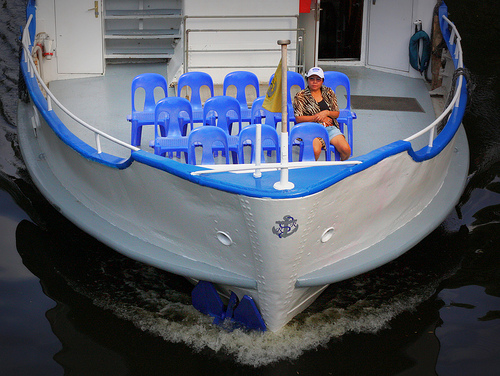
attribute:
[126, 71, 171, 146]
chair — blue, plastic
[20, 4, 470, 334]
boat — blue, white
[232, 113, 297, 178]
chair — plastic, blue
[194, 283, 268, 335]
anchor — blue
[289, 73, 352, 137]
shirt — Hawaiian 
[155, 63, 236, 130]
seat — blue, small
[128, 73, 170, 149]
blue chair — plastic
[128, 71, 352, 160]
chairs — blue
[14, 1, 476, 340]
ship — blue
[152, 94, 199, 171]
seat — blue, small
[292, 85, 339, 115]
shirt — brown 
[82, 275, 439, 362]
wave — small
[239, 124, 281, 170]
chair — blue, plastic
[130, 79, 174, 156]
seat — small, blue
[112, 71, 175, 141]
seat — small, blue